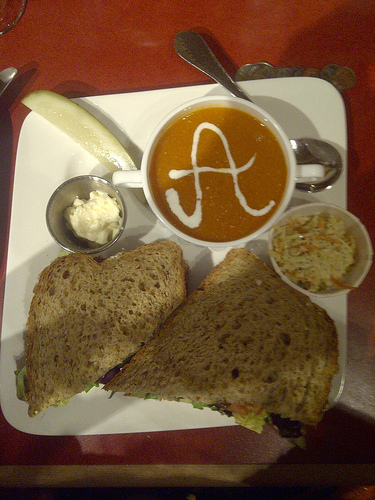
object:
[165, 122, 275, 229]
letter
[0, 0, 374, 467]
reddish countertop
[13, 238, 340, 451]
sandwich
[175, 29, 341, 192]
silver spoon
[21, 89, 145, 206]
pickle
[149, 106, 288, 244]
orange soup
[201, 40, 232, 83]
wall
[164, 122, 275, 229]
white liquid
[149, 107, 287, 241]
brown beverage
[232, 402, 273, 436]
lettuce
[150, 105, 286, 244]
sauce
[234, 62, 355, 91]
change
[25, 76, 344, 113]
edge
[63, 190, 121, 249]
butter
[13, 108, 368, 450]
food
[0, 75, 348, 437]
dinner plate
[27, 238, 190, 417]
bread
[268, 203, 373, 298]
bowl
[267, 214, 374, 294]
relish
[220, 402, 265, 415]
tomatoes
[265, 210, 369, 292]
coleslaw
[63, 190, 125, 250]
mayonnaise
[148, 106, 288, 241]
beverage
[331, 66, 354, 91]
coins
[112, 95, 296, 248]
bowl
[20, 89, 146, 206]
slice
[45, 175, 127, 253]
container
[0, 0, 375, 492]
table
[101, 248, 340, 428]
bread